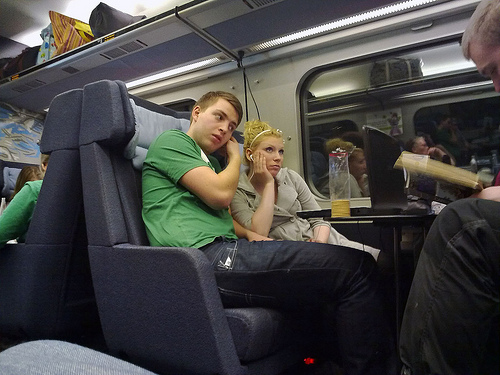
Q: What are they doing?
A: Relaxing.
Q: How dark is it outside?
A: Very dark.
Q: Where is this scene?
A: Train.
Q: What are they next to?
A: Window.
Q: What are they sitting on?
A: Large seats.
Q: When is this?
A: Nighttime.